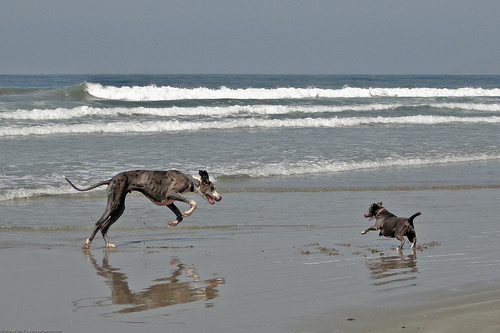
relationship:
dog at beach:
[61, 162, 224, 255] [6, 75, 498, 332]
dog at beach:
[359, 200, 422, 254] [6, 75, 498, 332]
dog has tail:
[359, 200, 422, 254] [410, 211, 420, 221]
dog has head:
[61, 162, 224, 255] [192, 168, 223, 205]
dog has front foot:
[61, 162, 224, 255] [169, 215, 185, 230]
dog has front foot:
[61, 162, 224, 255] [183, 202, 197, 215]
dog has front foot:
[359, 200, 422, 254] [361, 223, 377, 239]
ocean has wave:
[1, 81, 496, 197] [84, 80, 500, 102]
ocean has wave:
[1, 81, 496, 197] [3, 100, 500, 116]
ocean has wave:
[1, 81, 496, 197] [1, 114, 500, 129]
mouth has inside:
[205, 192, 219, 205] [207, 195, 215, 203]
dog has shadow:
[61, 162, 224, 255] [78, 243, 226, 315]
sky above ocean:
[0, 3, 498, 79] [1, 81, 496, 197]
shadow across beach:
[78, 243, 226, 315] [6, 75, 498, 332]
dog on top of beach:
[61, 162, 224, 255] [6, 75, 498, 332]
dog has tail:
[61, 162, 224, 255] [64, 172, 110, 198]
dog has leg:
[61, 162, 224, 255] [83, 188, 125, 249]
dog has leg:
[61, 162, 224, 255] [101, 188, 128, 248]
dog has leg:
[61, 162, 224, 255] [162, 196, 183, 229]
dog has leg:
[61, 162, 224, 255] [166, 176, 201, 217]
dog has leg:
[359, 200, 422, 254] [362, 220, 382, 238]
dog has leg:
[359, 200, 422, 254] [394, 232, 406, 253]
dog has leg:
[359, 200, 422, 254] [408, 233, 417, 248]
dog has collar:
[359, 200, 422, 254] [374, 205, 386, 218]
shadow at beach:
[78, 243, 226, 315] [6, 75, 498, 332]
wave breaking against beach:
[84, 80, 500, 102] [6, 75, 498, 332]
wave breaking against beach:
[3, 100, 500, 116] [6, 75, 498, 332]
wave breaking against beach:
[1, 114, 500, 129] [6, 75, 498, 332]